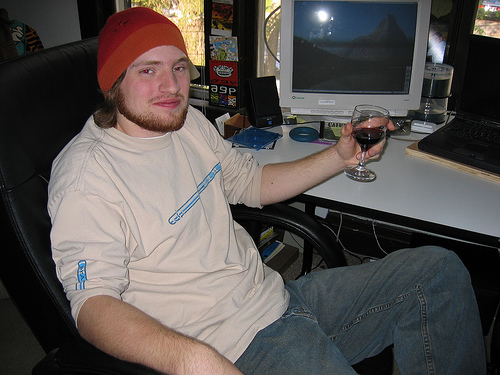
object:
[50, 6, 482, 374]
man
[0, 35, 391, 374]
chair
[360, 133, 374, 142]
wine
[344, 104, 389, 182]
wine glass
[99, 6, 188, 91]
hat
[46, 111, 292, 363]
shirt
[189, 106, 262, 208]
sleeve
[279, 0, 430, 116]
computer monitor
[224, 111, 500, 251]
table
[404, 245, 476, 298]
knee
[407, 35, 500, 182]
laptop computer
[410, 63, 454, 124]
stack of cds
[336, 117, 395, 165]
hand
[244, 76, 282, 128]
speaker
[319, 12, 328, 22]
reflection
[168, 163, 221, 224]
design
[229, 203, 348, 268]
arm rest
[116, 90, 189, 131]
facial hair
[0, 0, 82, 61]
wall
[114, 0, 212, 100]
window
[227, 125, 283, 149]
cd case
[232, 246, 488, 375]
jeans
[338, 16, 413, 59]
mountain reflection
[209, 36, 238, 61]
stickers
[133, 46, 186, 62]
forehead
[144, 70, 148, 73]
photo red eye